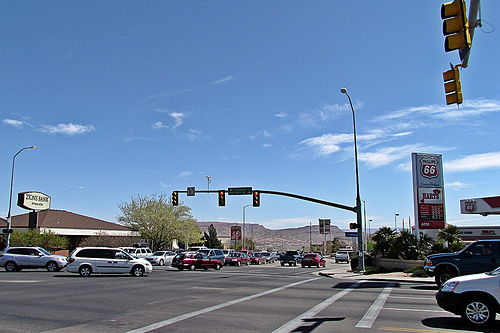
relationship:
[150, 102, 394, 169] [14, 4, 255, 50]
clouds in sky